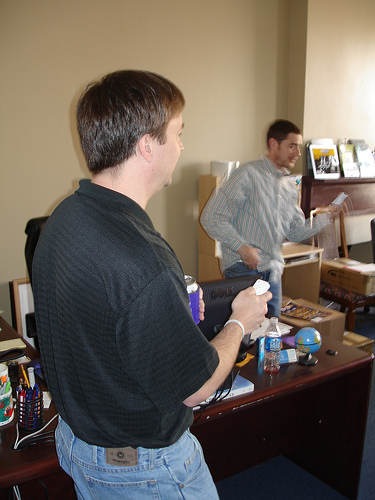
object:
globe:
[295, 328, 321, 354]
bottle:
[264, 316, 281, 372]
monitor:
[197, 270, 259, 324]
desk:
[0, 316, 373, 499]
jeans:
[230, 266, 283, 316]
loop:
[149, 450, 154, 471]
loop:
[91, 443, 96, 465]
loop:
[186, 424, 191, 434]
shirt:
[40, 203, 203, 450]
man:
[54, 78, 202, 500]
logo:
[107, 449, 137, 467]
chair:
[311, 202, 374, 338]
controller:
[252, 280, 270, 295]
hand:
[229, 288, 269, 329]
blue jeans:
[61, 432, 217, 497]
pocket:
[170, 432, 201, 471]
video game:
[250, 279, 273, 294]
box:
[323, 253, 373, 291]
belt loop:
[53, 412, 66, 426]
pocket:
[226, 267, 255, 276]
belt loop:
[68, 431, 76, 457]